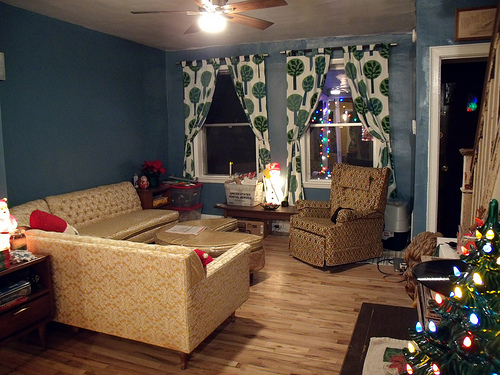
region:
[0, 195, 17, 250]
teddy bear santa figurine on table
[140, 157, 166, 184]
potted poinsetta plant on table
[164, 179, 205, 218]
two clear storage bins sitting in corner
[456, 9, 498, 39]
framed picture on wall atop doorway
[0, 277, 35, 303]
large book laying inside table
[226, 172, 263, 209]
postal bin sitting on table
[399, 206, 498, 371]
lighted christmas tree sitting in corner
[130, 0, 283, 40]
wooden ceiling fan attached to ceiling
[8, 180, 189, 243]
long tan leather couch sitting against wall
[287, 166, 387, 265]
armchair sitting in front of window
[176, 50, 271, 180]
Green and white curtains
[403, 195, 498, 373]
Lights on a ceramic Christmas tree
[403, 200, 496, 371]
A ceramic Christmas tree with lights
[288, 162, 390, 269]
A two-toned chair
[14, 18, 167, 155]
A blue wall in a living room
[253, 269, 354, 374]
A brown hardwood floor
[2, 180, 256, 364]
Couches in a living room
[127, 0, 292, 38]
A light and ceiling fan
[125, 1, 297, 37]
Brown blades on a ceiling fan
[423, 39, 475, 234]
White woodwork around a door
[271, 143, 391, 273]
chair next to a window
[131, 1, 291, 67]
ceiling fan with a light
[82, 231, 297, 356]
sofa in a living room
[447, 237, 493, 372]
christmas tree with lights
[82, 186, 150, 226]
sofa on a wall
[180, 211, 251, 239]
table next to a sofa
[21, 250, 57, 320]
table next to a sofa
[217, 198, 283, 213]
table next to window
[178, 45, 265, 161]
curtain on a window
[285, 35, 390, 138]
curtain on a window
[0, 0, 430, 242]
room with blue walls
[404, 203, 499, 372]
lights on ceramic tree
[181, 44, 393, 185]
two windows with curtains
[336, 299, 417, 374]
rug on wood floor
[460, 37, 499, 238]
railing on side of stairway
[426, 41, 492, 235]
white frame around open door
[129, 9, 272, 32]
glowing light of ceiling fan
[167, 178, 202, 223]
two containers with red covers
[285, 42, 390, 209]
white curtain with green trees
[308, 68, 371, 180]
light reflection on window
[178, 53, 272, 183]
Curtains on the window.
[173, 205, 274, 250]
Table in the center of room.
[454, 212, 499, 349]
Lights on the Christmas tree.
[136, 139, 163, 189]
A flower plant in the corner.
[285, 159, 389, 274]
A chair by the window.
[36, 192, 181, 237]
The sofa against the wall.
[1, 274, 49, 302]
Books under the table.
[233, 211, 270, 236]
A box under the table.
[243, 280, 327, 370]
The flooring is wooden.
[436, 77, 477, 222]
The door in the room.